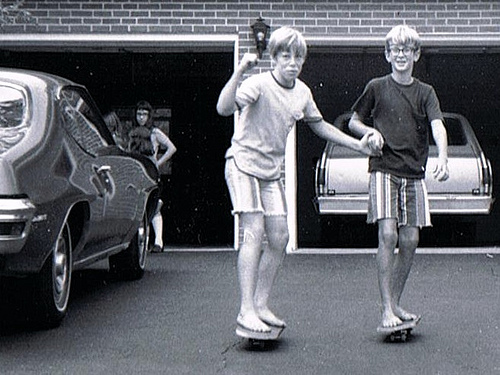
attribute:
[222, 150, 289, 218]
short — striped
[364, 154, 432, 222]
short — striped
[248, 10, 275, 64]
light — black, outdoor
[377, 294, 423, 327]
feet — bare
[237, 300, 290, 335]
feet — bare